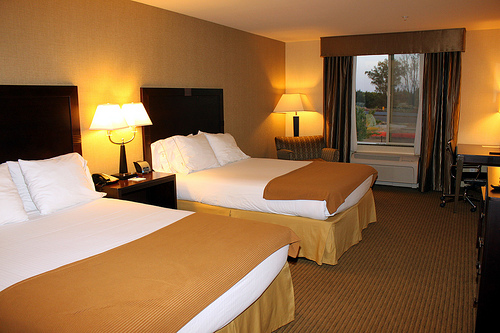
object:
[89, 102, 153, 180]
double lamp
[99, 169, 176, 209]
nightstand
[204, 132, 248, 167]
pillows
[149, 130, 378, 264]
bed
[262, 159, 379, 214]
blanket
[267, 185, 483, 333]
carpet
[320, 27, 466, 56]
valance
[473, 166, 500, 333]
dresser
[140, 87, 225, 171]
headboard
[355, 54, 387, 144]
window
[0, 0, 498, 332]
room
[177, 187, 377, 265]
dust ruffle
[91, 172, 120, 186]
phone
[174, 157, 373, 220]
sheets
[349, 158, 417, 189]
heat and ac unit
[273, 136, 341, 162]
chair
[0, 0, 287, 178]
wall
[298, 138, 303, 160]
lines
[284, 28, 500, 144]
walls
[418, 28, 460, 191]
curtains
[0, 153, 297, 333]
beds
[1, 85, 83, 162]
headboards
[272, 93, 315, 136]
lamp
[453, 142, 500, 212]
desk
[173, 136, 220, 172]
pillow